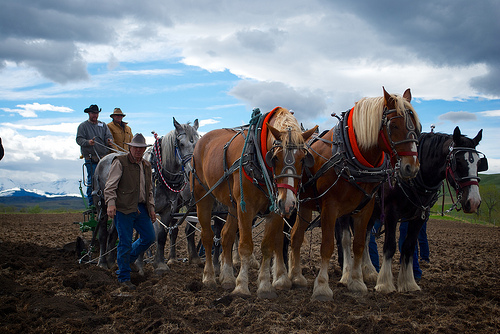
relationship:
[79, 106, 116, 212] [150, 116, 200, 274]
man behind horse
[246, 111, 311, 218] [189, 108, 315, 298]
bridle on horse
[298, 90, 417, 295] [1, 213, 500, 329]
horse in dirt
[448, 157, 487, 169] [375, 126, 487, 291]
blinder on horse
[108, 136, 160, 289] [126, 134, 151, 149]
man wearing cowboy hat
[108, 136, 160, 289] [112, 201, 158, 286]
man wearing jeans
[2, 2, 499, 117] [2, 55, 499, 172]
cloud in sky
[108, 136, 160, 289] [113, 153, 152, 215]
man wearing vest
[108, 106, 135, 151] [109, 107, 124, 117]
man wearing cowboy hat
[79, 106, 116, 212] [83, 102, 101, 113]
man wearing cowboy hat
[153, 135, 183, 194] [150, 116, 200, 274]
bridle on horse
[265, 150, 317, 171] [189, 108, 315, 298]
blinder on horse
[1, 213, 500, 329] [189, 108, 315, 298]
dirt underneath horse